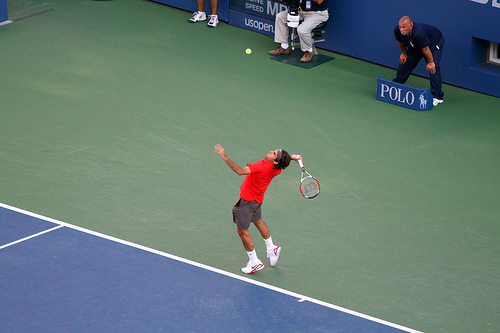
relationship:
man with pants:
[266, 1, 331, 64] [271, 8, 327, 50]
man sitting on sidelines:
[266, 1, 331, 64] [143, 0, 497, 109]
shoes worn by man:
[240, 258, 265, 274] [213, 142, 305, 274]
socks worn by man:
[244, 236, 276, 262] [213, 142, 305, 274]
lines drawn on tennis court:
[3, 204, 422, 331] [5, 0, 496, 330]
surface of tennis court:
[1, 0, 499, 330] [5, 0, 496, 330]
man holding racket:
[213, 140, 301, 273] [298, 154, 321, 200]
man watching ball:
[213, 142, 305, 274] [243, 48, 252, 54]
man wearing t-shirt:
[213, 142, 305, 274] [230, 160, 288, 208]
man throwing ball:
[213, 142, 305, 274] [243, 48, 252, 54]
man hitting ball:
[213, 142, 305, 274] [232, 39, 258, 59]